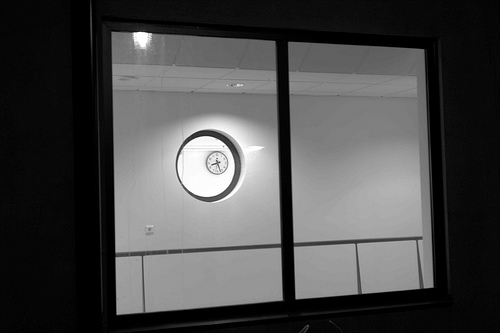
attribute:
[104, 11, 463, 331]
double window — open, paned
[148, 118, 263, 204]
clock — seen through window, saying 8:27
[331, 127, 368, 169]
wall — white, outside building, inside building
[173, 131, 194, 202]
window — round, glass, in building, large, hole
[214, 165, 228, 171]
hands — black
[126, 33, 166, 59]
light — very bright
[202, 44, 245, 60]
ceiling — in building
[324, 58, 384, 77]
window pane — black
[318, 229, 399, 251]
railing — black, inside building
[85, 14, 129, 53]
frame — metal